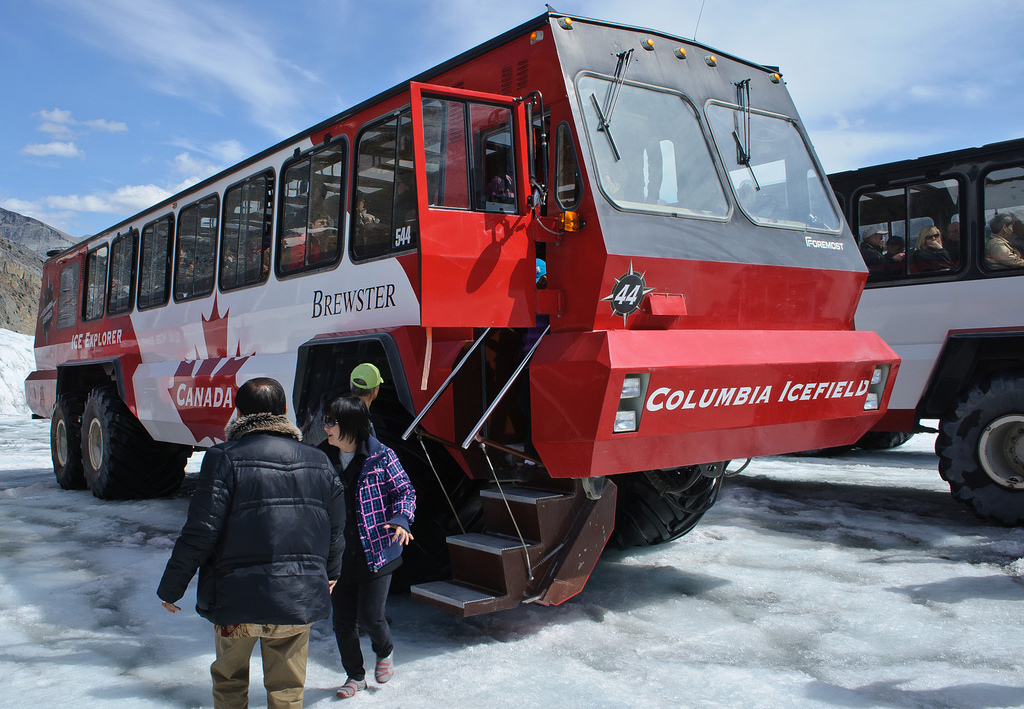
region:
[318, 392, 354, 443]
woman in dark hair is wearing shades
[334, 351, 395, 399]
neon yellow-green ball cap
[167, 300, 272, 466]
Canadian maple leaf on bus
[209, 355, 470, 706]
Men boarding a bus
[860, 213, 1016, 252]
People looking out bus window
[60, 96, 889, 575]
large bus on elevated wheels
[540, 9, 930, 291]
square front compartment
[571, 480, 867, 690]
patched ice ground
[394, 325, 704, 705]
extendable stairs for bus access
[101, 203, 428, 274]
people waiting on the bus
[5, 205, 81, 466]
mountain in the distance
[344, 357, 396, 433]
man wearing green hat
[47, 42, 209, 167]
blue sky with white clouds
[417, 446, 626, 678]
stairs on a truck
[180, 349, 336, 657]
man with black coat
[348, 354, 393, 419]
man with green hat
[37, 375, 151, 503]
truck tires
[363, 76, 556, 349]
red truck door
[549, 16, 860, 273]
truck windshield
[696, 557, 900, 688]
snow and ice on the ground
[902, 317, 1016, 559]
truck tire with white rim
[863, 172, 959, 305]
people on a white truck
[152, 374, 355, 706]
man walking in snow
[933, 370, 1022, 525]
snow tire with large treds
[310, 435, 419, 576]
blue and violet plaid jacket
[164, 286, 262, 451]
red Canadian maple leaf symbol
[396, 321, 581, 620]
drop down stairs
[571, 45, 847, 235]
two windows with windshield wipers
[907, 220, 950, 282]
blond woman looking out window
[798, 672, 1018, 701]
puddle of melted snow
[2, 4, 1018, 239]
blue sky with scattered clouds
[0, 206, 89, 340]
hill in the distance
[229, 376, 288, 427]
the back of a man's head which has black hair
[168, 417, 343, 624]
a black winter jacket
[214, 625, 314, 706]
a pair of tan pants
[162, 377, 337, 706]
a man with his back to the camera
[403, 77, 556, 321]
the red door of a vehicle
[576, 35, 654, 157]
the windshield wiper on the vehicle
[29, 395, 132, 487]
two back tires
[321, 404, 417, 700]
a woman with black hair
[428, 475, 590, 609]
steps leading up to the vehicle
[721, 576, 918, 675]
Snow on the ground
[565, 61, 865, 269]
Two front windows of a bus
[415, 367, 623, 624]
Stairs leading up to a bus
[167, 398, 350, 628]
Man wearing black leather jacket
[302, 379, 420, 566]
Woman wearing a purple jacket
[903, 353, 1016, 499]
A big black tire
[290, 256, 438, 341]
The side of a bus reads "BREWSTER"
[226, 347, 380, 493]
People have black hair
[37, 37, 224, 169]
White clouds in the sky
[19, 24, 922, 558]
A bus is white and red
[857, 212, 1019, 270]
people sitting in a large vehicle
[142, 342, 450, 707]
people standing on the snow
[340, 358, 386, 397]
a man wearing a green hat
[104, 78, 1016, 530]
two large vehicles standing in the snow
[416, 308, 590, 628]
steps allowing access to vehicle's interior have been let down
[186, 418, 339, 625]
man wearing black jacket with a fur collar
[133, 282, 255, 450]
design on vehicle indicating it is Canadian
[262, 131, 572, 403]
the vehicle is red and white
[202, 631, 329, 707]
the man is wearing tan colored pants